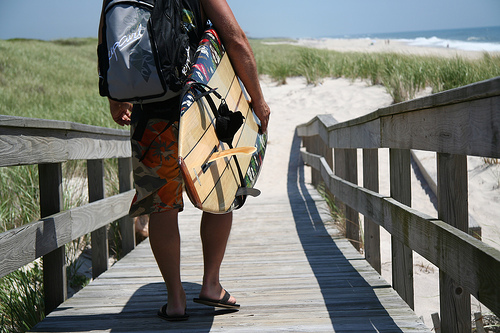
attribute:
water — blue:
[310, 25, 499, 45]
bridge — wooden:
[0, 74, 499, 332]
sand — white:
[0, 37, 499, 333]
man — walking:
[97, 0, 270, 322]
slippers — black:
[157, 289, 240, 320]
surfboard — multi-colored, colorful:
[177, 17, 268, 214]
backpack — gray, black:
[97, 0, 191, 105]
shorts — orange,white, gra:
[129, 120, 185, 217]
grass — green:
[0, 38, 498, 331]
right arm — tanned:
[201, 1, 270, 134]